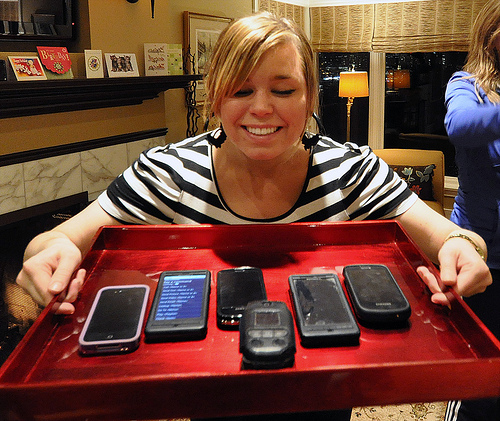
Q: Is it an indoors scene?
A: Yes, it is indoors.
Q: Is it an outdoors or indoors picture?
A: It is indoors.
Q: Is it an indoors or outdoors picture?
A: It is indoors.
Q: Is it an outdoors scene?
A: No, it is indoors.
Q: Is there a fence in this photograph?
A: No, there are no fences.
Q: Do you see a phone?
A: Yes, there is a phone.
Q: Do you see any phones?
A: Yes, there is a phone.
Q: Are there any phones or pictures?
A: Yes, there is a phone.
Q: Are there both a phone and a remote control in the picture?
A: No, there is a phone but no remote controls.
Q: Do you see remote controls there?
A: No, there are no remote controls.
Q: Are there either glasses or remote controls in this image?
A: No, there are no remote controls or glasses.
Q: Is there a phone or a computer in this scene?
A: Yes, there is a phone.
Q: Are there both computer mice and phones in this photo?
A: No, there is a phone but no computer mice.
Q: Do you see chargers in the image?
A: No, there are no chargers.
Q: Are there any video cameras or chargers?
A: No, there are no chargers or video cameras.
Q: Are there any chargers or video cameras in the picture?
A: No, there are no chargers or video cameras.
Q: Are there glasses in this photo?
A: No, there are no glasses.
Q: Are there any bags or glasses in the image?
A: No, there are no glasses or bags.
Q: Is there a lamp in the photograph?
A: Yes, there is a lamp.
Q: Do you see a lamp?
A: Yes, there is a lamp.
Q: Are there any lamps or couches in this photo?
A: Yes, there is a lamp.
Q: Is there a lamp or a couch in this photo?
A: Yes, there is a lamp.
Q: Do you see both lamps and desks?
A: No, there is a lamp but no desks.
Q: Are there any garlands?
A: No, there are no garlands.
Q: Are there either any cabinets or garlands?
A: No, there are no garlands or cabinets.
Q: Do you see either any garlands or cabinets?
A: No, there are no garlands or cabinets.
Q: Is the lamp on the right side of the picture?
A: Yes, the lamp is on the right of the image.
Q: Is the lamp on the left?
A: No, the lamp is on the right of the image.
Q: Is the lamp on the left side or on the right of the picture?
A: The lamp is on the right of the image.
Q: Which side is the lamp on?
A: The lamp is on the right of the image.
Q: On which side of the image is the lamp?
A: The lamp is on the right of the image.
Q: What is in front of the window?
A: The lamp is in front of the window.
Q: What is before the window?
A: The lamp is in front of the window.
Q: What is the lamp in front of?
A: The lamp is in front of the window.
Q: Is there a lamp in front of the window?
A: Yes, there is a lamp in front of the window.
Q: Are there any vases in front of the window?
A: No, there is a lamp in front of the window.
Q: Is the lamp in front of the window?
A: Yes, the lamp is in front of the window.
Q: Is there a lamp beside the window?
A: Yes, there is a lamp beside the window.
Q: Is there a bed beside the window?
A: No, there is a lamp beside the window.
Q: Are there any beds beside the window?
A: No, there is a lamp beside the window.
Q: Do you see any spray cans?
A: No, there are no spray cans.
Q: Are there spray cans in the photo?
A: No, there are no spray cans.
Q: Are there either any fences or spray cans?
A: No, there are no spray cans or fences.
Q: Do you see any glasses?
A: No, there are no glasses.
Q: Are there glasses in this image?
A: No, there are no glasses.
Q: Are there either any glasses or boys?
A: No, there are no glasses or boys.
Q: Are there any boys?
A: No, there are no boys.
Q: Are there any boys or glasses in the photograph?
A: No, there are no boys or glasses.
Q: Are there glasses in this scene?
A: No, there are no glasses.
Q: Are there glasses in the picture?
A: No, there are no glasses.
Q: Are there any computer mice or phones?
A: Yes, there is a phone.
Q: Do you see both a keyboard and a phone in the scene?
A: No, there is a phone but no keyboards.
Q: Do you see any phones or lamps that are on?
A: Yes, the phone is on.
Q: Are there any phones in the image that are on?
A: Yes, there is a phone that is on.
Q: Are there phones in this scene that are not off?
A: Yes, there is a phone that is on.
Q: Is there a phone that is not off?
A: Yes, there is a phone that is on.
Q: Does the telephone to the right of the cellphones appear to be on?
A: Yes, the telephone is on.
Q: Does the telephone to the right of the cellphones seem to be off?
A: No, the phone is on.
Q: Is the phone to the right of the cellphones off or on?
A: The telephone is on.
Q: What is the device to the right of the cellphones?
A: The device is a phone.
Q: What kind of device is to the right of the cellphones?
A: The device is a phone.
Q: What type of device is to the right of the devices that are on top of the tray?
A: The device is a phone.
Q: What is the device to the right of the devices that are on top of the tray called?
A: The device is a phone.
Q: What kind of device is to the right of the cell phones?
A: The device is a phone.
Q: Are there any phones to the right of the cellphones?
A: Yes, there is a phone to the right of the cellphones.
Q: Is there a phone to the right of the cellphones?
A: Yes, there is a phone to the right of the cellphones.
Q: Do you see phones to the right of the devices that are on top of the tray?
A: Yes, there is a phone to the right of the cellphones.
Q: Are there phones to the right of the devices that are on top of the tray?
A: Yes, there is a phone to the right of the cellphones.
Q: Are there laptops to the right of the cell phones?
A: No, there is a phone to the right of the cell phones.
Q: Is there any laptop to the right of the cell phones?
A: No, there is a phone to the right of the cell phones.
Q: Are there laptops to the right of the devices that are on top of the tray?
A: No, there is a phone to the right of the cell phones.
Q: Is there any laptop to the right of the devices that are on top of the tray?
A: No, there is a phone to the right of the cell phones.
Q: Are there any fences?
A: No, there are no fences.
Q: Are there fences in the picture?
A: No, there are no fences.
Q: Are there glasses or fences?
A: No, there are no fences or glasses.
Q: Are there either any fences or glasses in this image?
A: No, there are no fences or glasses.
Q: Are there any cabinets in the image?
A: No, there are no cabinets.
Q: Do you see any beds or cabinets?
A: No, there are no cabinets or beds.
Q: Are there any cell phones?
A: Yes, there are cell phones.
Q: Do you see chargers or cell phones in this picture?
A: Yes, there are cell phones.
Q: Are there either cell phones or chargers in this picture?
A: Yes, there are cell phones.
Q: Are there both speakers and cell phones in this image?
A: No, there are cell phones but no speakers.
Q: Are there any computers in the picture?
A: No, there are no computers.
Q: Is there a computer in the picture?
A: No, there are no computers.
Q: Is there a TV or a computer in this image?
A: No, there are no computers or televisions.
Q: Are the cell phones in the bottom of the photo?
A: Yes, the cell phones are in the bottom of the image.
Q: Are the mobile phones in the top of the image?
A: No, the mobile phones are in the bottom of the image.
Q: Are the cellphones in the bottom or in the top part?
A: The cellphones are in the bottom of the image.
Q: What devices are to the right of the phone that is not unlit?
A: The devices are cell phones.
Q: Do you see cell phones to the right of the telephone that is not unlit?
A: Yes, there are cell phones to the right of the telephone.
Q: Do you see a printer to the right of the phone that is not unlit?
A: No, there are cell phones to the right of the phone.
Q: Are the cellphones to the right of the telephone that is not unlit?
A: Yes, the cellphones are to the right of the phone.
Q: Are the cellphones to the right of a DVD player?
A: No, the cellphones are to the right of the phone.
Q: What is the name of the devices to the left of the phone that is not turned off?
A: The devices are cell phones.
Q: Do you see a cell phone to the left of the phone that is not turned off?
A: Yes, there are cell phones to the left of the phone.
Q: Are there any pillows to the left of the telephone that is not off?
A: No, there are cell phones to the left of the telephone.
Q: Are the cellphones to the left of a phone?
A: Yes, the cellphones are to the left of a phone.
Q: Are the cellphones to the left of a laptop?
A: No, the cellphones are to the left of a phone.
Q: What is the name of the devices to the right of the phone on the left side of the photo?
A: The devices are cell phones.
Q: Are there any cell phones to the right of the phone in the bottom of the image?
A: Yes, there are cell phones to the right of the telephone.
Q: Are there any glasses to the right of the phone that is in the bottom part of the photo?
A: No, there are cell phones to the right of the phone.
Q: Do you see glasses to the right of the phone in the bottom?
A: No, there are cell phones to the right of the phone.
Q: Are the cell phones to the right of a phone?
A: Yes, the cell phones are to the right of a phone.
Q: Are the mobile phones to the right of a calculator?
A: No, the mobile phones are to the right of a phone.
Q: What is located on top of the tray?
A: The cellphones are on top of the tray.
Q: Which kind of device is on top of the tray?
A: The devices are cell phones.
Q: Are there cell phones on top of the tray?
A: Yes, there are cell phones on top of the tray.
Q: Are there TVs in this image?
A: No, there are no tvs.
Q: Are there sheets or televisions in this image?
A: No, there are no televisions or sheets.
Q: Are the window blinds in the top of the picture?
A: Yes, the blinds are in the top of the image.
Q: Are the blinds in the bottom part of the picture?
A: No, the blinds are in the top of the image.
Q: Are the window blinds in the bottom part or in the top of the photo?
A: The blinds are in the top of the image.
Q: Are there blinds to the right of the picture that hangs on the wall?
A: Yes, there are blinds to the right of the picture.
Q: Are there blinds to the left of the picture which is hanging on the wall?
A: No, the blinds are to the right of the picture.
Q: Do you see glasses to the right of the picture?
A: No, there are blinds to the right of the picture.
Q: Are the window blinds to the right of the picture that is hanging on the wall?
A: Yes, the blinds are to the right of the picture.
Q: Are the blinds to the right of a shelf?
A: No, the blinds are to the right of the picture.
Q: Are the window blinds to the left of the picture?
A: No, the blinds are to the right of the picture.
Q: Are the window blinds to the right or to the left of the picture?
A: The blinds are to the right of the picture.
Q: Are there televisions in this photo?
A: No, there are no televisions.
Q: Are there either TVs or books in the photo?
A: No, there are no TVs or books.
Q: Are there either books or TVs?
A: No, there are no TVs or books.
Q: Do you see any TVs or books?
A: No, there are no TVs or books.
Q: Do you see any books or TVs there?
A: No, there are no TVs or books.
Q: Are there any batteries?
A: No, there are no batteries.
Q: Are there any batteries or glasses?
A: No, there are no batteries or glasses.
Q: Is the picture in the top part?
A: Yes, the picture is in the top of the image.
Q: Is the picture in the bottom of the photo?
A: No, the picture is in the top of the image.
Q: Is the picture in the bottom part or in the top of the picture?
A: The picture is in the top of the image.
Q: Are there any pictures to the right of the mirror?
A: Yes, there is a picture to the right of the mirror.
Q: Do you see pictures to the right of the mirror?
A: Yes, there is a picture to the right of the mirror.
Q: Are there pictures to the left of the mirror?
A: No, the picture is to the right of the mirror.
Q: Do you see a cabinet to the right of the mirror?
A: No, there is a picture to the right of the mirror.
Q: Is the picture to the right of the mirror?
A: Yes, the picture is to the right of the mirror.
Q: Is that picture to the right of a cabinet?
A: No, the picture is to the right of the mirror.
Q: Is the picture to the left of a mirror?
A: No, the picture is to the right of a mirror.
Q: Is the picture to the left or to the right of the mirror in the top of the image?
A: The picture is to the right of the mirror.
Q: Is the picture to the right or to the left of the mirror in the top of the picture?
A: The picture is to the right of the mirror.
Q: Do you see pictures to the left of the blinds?
A: Yes, there is a picture to the left of the blinds.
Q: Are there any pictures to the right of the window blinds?
A: No, the picture is to the left of the blinds.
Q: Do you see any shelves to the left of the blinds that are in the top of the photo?
A: No, there is a picture to the left of the blinds.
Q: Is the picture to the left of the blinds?
A: Yes, the picture is to the left of the blinds.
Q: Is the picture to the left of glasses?
A: No, the picture is to the left of the blinds.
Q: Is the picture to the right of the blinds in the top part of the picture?
A: No, the picture is to the left of the blinds.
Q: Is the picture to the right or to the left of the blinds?
A: The picture is to the left of the blinds.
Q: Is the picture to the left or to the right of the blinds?
A: The picture is to the left of the blinds.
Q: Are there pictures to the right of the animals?
A: Yes, there is a picture to the right of the animals.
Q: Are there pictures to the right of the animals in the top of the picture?
A: Yes, there is a picture to the right of the animals.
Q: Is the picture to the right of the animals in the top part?
A: Yes, the picture is to the right of the animals.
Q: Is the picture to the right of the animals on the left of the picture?
A: Yes, the picture is to the right of the animals.